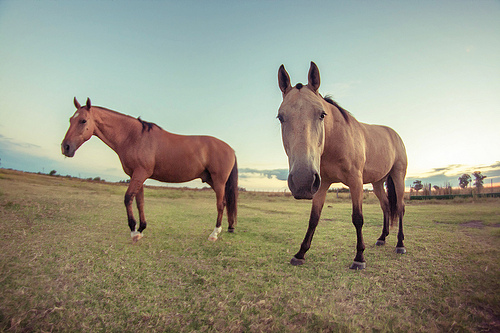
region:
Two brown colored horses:
[45, 60, 433, 284]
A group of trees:
[410, 165, 499, 207]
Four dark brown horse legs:
[276, 205, 421, 285]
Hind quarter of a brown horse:
[202, 132, 238, 200]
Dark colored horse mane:
[87, 102, 167, 137]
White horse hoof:
[197, 221, 227, 249]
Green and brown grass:
[35, 266, 480, 326]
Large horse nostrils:
[280, 160, 322, 206]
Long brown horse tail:
[220, 145, 245, 250]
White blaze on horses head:
[66, 103, 87, 134]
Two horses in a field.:
[17, 65, 477, 295]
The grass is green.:
[172, 243, 240, 286]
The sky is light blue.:
[108, 12, 425, 50]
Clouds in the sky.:
[240, 156, 285, 181]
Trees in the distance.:
[410, 156, 496, 211]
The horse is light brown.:
[260, 45, 416, 275]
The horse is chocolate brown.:
[47, 87, 248, 247]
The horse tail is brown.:
[222, 156, 243, 222]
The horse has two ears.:
[267, 60, 328, 95]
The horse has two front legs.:
[286, 202, 374, 278]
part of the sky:
[161, 3, 206, 48]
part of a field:
[236, 198, 273, 245]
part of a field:
[198, 188, 237, 283]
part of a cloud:
[426, 152, 453, 186]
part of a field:
[204, 256, 251, 323]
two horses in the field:
[33, 80, 434, 298]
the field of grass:
[28, 192, 378, 326]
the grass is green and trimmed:
[36, 211, 431, 324]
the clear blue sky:
[144, 23, 233, 63]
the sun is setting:
[428, 160, 492, 195]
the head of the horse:
[271, 57, 331, 194]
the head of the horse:
[49, 90, 110, 174]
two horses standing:
[17, 81, 452, 271]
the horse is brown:
[36, 87, 241, 249]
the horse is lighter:
[270, 45, 422, 267]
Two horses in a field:
[28, 67, 490, 320]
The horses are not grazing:
[43, 68, 440, 302]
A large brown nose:
[280, 157, 334, 202]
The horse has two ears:
[272, 52, 327, 101]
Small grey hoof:
[345, 257, 372, 273]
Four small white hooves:
[123, 217, 227, 248]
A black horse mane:
[324, 91, 348, 122]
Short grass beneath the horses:
[60, 247, 238, 323]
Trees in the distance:
[425, 176, 488, 197]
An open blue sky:
[110, 36, 227, 82]